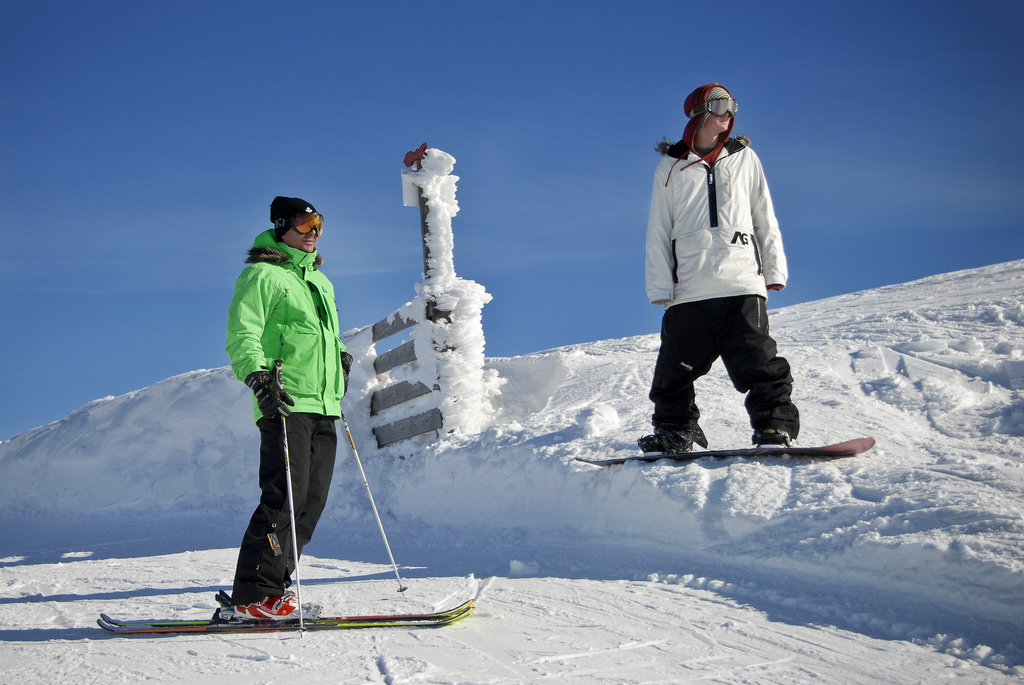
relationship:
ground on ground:
[0, 260, 1024, 684] [0, 260, 1022, 681]